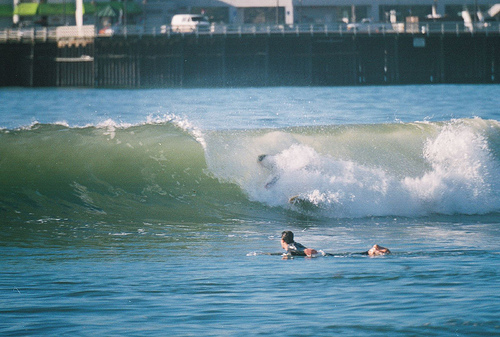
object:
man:
[281, 230, 319, 260]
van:
[171, 13, 211, 34]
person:
[255, 153, 332, 216]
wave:
[265, 118, 493, 219]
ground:
[340, 161, 392, 205]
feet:
[368, 244, 393, 259]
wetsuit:
[281, 242, 309, 255]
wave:
[0, 115, 500, 220]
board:
[246, 244, 391, 259]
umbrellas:
[10, 0, 22, 24]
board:
[287, 196, 327, 217]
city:
[0, 0, 500, 38]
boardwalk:
[0, 21, 500, 90]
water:
[0, 83, 500, 336]